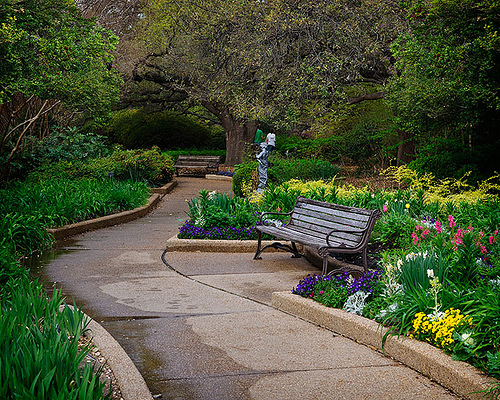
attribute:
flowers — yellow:
[237, 162, 498, 204]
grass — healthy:
[0, 130, 493, 395]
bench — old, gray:
[264, 188, 380, 302]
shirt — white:
[264, 132, 276, 145]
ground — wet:
[58, 223, 205, 398]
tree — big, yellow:
[108, 7, 356, 167]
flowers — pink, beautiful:
[373, 141, 495, 336]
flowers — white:
[380, 246, 430, 317]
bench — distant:
[175, 153, 221, 176]